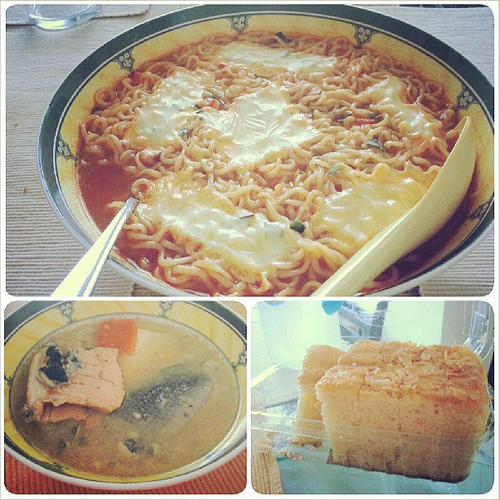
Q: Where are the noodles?
A: Bowl at the top.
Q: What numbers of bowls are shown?
A: 2.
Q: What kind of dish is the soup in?
A: Bowl.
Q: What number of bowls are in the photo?
A: 2.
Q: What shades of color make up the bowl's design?
A: Green and yellow.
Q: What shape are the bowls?
A: Round.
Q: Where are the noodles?
A: In the top bowl.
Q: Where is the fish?
A: In bowl to the left.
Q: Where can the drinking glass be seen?
A: Above the top bowl.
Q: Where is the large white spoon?
A: In the top bowl.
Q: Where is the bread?
A: The bottom right photo.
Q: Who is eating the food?
A: Nobody is in the picture.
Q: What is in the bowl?
A: Soup.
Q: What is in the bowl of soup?
A: Noodles.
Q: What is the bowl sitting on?
A: Table.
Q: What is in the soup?
A: Spoon.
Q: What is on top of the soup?
A: Cheese.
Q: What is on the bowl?
A: Pattern.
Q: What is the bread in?
A: Plastic container.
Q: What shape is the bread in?
A: Square.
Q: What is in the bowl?
A: Some soup.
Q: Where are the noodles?
A: A bowl.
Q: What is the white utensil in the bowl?
A: A spoon.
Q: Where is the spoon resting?
A: In the bowl.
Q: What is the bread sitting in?
A: Plastic tray.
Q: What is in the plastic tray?
A: Bread.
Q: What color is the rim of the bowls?
A: Green.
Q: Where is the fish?
A: The soup.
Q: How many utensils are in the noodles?
A: Two.